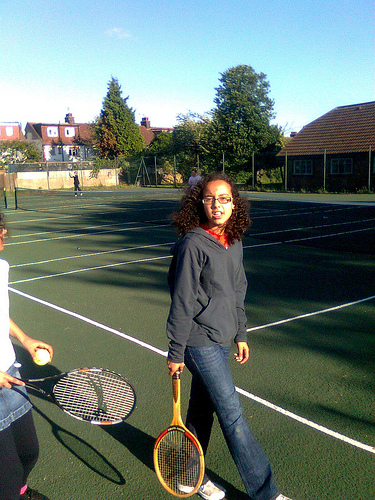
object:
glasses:
[202, 195, 233, 204]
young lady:
[165, 172, 293, 499]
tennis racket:
[153, 372, 205, 500]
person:
[0, 213, 54, 498]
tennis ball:
[34, 347, 50, 367]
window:
[292, 159, 311, 175]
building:
[277, 98, 375, 198]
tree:
[90, 72, 145, 172]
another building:
[24, 112, 158, 160]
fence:
[8, 150, 375, 195]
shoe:
[177, 480, 227, 498]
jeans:
[177, 345, 280, 499]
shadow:
[34, 405, 127, 487]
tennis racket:
[0, 367, 136, 425]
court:
[0, 188, 374, 496]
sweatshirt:
[166, 234, 249, 362]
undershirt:
[205, 228, 231, 247]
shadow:
[12, 343, 153, 472]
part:
[197, 17, 342, 64]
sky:
[0, 0, 374, 125]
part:
[75, 373, 126, 413]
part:
[240, 433, 264, 480]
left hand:
[234, 341, 252, 366]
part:
[100, 322, 142, 350]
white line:
[8, 282, 168, 360]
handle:
[170, 375, 184, 422]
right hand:
[165, 358, 186, 380]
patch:
[47, 225, 168, 294]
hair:
[172, 172, 252, 244]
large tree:
[198, 61, 285, 184]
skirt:
[0, 362, 33, 434]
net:
[14, 185, 181, 229]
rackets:
[8, 365, 204, 497]